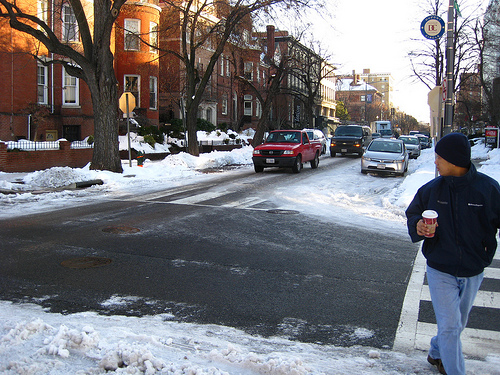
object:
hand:
[415, 219, 434, 237]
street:
[46, 204, 367, 333]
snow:
[163, 156, 201, 175]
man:
[403, 132, 499, 368]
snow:
[3, 336, 161, 375]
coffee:
[420, 209, 440, 238]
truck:
[252, 128, 328, 174]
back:
[118, 92, 137, 116]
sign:
[119, 90, 137, 118]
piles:
[161, 151, 231, 170]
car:
[360, 136, 411, 178]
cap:
[433, 131, 473, 163]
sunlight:
[1, 3, 204, 79]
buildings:
[1, 0, 163, 161]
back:
[401, 122, 490, 202]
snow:
[32, 167, 85, 184]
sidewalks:
[0, 140, 210, 219]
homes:
[330, 10, 387, 132]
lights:
[331, 143, 335, 147]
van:
[329, 125, 372, 156]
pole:
[435, 14, 469, 139]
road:
[0, 192, 374, 338]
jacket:
[402, 173, 500, 276]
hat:
[432, 133, 487, 170]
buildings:
[156, 5, 257, 138]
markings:
[216, 172, 265, 214]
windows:
[123, 17, 142, 51]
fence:
[17, 130, 87, 152]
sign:
[485, 127, 499, 150]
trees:
[419, 5, 491, 93]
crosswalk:
[364, 244, 458, 358]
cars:
[250, 127, 323, 178]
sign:
[418, 15, 444, 38]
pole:
[432, 39, 447, 104]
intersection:
[47, 96, 443, 262]